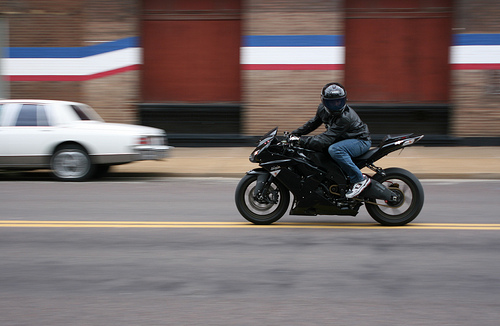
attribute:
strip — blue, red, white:
[230, 24, 350, 75]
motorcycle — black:
[229, 115, 433, 225]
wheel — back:
[362, 167, 422, 228]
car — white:
[0, 95, 179, 183]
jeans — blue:
[320, 146, 360, 185]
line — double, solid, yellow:
[1, 218, 499, 230]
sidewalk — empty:
[117, 145, 499, 187]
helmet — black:
[319, 82, 348, 117]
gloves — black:
[295, 137, 308, 146]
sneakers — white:
[340, 173, 376, 201]